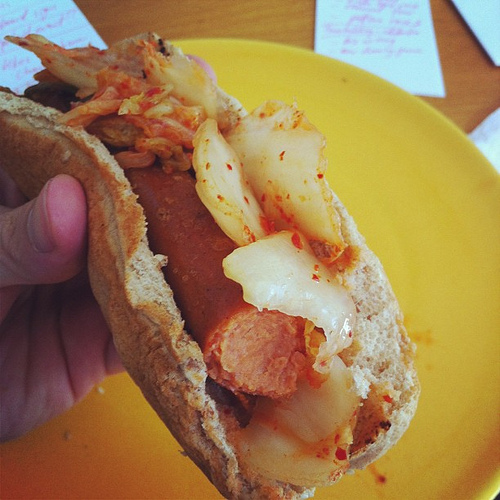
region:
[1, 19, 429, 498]
Hot dog with sauce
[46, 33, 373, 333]
Vegetables on hot dog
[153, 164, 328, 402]
Hot dog is eaten a piece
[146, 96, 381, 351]
Slices of cucumber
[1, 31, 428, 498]
Hand holding a hot dog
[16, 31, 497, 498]
Yellow dish under a hand with a hot dog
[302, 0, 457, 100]
Piece of paper with handwriting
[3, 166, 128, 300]
Thumb grabbing a hot dog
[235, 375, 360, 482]
Vegetables below hot dog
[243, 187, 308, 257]
Res spices over vegetables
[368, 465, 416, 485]
small red spot on yellow plate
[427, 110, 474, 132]
edge of yellow plate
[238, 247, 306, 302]
gooey white chees on plate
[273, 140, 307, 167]
small ketchup spot on onion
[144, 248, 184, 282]
tiny white piece of bread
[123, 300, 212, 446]
crusted edge of bread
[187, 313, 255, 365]
outer edge of polish sausage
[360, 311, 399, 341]
small holes in the bread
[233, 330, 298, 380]
pink inside of sausage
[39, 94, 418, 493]
large polish sausage sandwich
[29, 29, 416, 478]
hot dog in a bun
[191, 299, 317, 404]
bite taken out of end of hot dog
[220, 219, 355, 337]
onion on top of hot dog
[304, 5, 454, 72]
paper with writing on it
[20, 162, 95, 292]
thumb on side of bun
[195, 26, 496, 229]
yellow plate for hot dog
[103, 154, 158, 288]
toasted edge of bun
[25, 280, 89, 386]
wrinkle in palm of hand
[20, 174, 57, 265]
trimmed nail on thumb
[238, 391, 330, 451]
onion underneath hot dog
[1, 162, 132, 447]
hand holding hot dog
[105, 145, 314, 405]
hot dog on a bun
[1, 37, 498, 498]
yellow plate under hot dog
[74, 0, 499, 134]
brown table under plate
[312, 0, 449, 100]
white paper with red writing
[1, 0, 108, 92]
white paper with red writing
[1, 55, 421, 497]
brown bun holding hot dog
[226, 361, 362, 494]
big white onions on hot dog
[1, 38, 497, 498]
yellow plate is round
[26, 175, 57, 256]
fingernail on thumb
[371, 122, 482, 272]
the plate is yellow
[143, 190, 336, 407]
the hotdog is pink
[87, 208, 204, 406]
the bread is brown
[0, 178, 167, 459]
the person is white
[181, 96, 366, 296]
the onions are white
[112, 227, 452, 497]
the hotdog is bitten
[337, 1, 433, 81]
the text is pink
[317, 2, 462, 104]
the paper is white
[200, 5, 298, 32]
the desk is brown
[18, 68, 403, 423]
the person is holding the hotdog